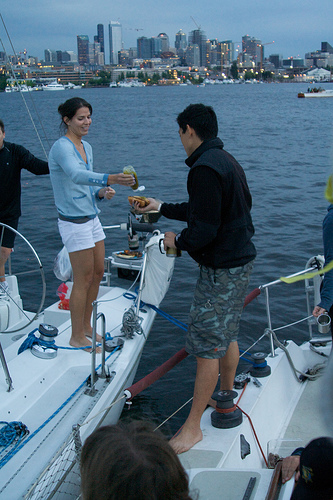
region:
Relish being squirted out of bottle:
[121, 164, 145, 193]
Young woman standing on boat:
[47, 96, 135, 353]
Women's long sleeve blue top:
[47, 137, 107, 218]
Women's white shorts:
[56, 216, 104, 252]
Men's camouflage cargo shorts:
[185, 262, 253, 359]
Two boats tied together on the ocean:
[0, 221, 326, 496]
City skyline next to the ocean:
[2, 19, 332, 89]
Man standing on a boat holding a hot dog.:
[128, 102, 256, 453]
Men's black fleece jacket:
[159, 136, 255, 268]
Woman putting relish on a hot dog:
[47, 96, 156, 353]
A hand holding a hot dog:
[123, 191, 161, 212]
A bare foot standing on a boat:
[163, 415, 206, 459]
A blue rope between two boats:
[132, 301, 275, 370]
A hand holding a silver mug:
[309, 303, 330, 335]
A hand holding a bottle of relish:
[109, 161, 147, 193]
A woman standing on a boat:
[40, 91, 148, 362]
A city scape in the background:
[2, 7, 326, 78]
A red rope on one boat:
[216, 390, 272, 473]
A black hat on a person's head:
[296, 439, 332, 493]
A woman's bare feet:
[67, 326, 107, 357]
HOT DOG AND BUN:
[125, 193, 156, 211]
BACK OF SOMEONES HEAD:
[76, 416, 194, 497]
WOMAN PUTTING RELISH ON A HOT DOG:
[47, 93, 154, 359]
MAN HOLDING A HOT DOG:
[125, 97, 257, 456]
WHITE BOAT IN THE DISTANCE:
[35, 76, 70, 93]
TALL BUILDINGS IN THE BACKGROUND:
[69, 19, 131, 65]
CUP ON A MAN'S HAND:
[154, 228, 183, 260]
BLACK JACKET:
[158, 135, 266, 273]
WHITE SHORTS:
[50, 211, 108, 254]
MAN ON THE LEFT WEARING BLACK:
[0, 116, 57, 306]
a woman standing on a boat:
[40, 92, 121, 361]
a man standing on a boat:
[169, 94, 248, 360]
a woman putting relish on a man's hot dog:
[51, 95, 252, 231]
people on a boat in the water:
[287, 84, 332, 113]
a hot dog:
[127, 190, 151, 214]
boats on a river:
[6, 76, 294, 92]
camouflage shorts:
[186, 260, 254, 359]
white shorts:
[53, 213, 115, 252]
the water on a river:
[101, 92, 175, 160]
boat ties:
[212, 350, 275, 433]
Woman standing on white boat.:
[33, 94, 121, 353]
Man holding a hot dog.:
[126, 194, 153, 208]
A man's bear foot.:
[161, 424, 213, 460]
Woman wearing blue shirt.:
[44, 136, 118, 226]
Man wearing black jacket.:
[156, 142, 265, 270]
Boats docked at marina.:
[42, 79, 148, 93]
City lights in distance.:
[133, 24, 284, 78]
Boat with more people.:
[296, 84, 330, 101]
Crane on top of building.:
[187, 13, 206, 34]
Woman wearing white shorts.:
[54, 215, 112, 257]